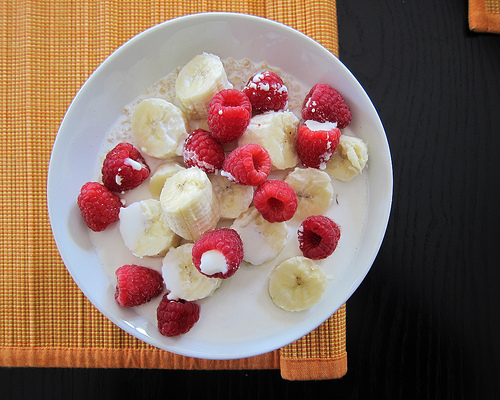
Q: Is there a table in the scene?
A: Yes, there is a table.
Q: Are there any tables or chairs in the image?
A: Yes, there is a table.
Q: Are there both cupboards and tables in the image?
A: No, there is a table but no cupboards.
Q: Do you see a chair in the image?
A: No, there are no chairs.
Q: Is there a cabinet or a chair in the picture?
A: No, there are no chairs or cabinets.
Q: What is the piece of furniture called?
A: The piece of furniture is a table.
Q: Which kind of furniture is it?
A: The piece of furniture is a table.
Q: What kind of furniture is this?
A: This is a table.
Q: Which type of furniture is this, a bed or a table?
A: This is a table.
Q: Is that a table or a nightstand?
A: That is a table.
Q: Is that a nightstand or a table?
A: That is a table.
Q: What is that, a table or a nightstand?
A: That is a table.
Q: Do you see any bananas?
A: Yes, there are bananas.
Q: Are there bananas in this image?
A: Yes, there are bananas.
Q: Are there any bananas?
A: Yes, there are bananas.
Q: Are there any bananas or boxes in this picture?
A: Yes, there are bananas.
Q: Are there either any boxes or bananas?
A: Yes, there are bananas.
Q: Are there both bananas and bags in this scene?
A: No, there are bananas but no bags.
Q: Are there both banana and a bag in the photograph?
A: No, there are bananas but no bags.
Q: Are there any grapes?
A: No, there are no grapes.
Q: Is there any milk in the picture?
A: Yes, there is milk.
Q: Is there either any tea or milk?
A: Yes, there is milk.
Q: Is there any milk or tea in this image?
A: Yes, there is milk.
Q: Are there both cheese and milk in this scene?
A: No, there is milk but no cheese.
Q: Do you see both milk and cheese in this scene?
A: No, there is milk but no cheese.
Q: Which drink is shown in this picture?
A: The drink is milk.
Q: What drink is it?
A: The drink is milk.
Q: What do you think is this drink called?
A: This is milk.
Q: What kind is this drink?
A: This is milk.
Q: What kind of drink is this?
A: This is milk.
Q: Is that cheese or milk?
A: That is milk.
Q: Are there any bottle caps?
A: No, there are no bottle caps.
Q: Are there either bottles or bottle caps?
A: No, there are no bottle caps or bottles.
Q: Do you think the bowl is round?
A: Yes, the bowl is round.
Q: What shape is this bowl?
A: The bowl is round.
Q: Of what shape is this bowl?
A: The bowl is round.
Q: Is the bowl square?
A: No, the bowl is round.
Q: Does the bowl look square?
A: No, the bowl is round.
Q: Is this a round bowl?
A: Yes, this is a round bowl.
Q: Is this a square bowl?
A: No, this is a round bowl.